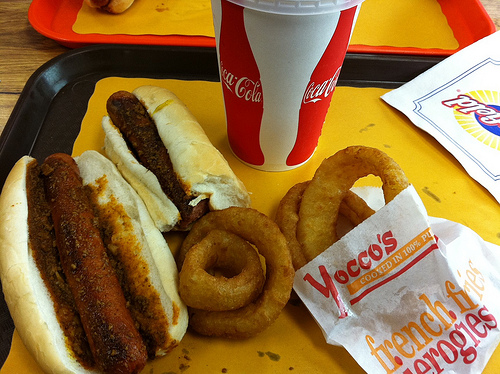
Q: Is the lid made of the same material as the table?
A: No, the lid is made of plastic and the table is made of wood.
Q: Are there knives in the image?
A: No, there are no knives.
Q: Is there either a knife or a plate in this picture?
A: No, there are no knives or plates.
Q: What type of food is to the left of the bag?
A: The food is onion rings.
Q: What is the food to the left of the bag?
A: The food is onion rings.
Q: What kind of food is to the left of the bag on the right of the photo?
A: The food is onion rings.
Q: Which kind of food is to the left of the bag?
A: The food is onion rings.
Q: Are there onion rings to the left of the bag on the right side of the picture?
A: Yes, there are onion rings to the left of the bag.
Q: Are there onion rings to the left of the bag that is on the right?
A: Yes, there are onion rings to the left of the bag.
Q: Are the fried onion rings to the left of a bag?
A: Yes, the onion rings are to the left of a bag.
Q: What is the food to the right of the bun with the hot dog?
A: The food is onion rings.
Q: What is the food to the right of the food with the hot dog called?
A: The food is onion rings.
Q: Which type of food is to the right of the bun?
A: The food is onion rings.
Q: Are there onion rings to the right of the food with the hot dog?
A: Yes, there are onion rings to the right of the bun.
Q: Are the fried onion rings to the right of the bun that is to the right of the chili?
A: Yes, the onion rings are to the right of the bun.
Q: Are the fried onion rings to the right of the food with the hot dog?
A: Yes, the onion rings are to the right of the bun.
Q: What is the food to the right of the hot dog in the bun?
A: The food is onion rings.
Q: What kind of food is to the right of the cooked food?
A: The food is onion rings.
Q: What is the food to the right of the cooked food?
A: The food is onion rings.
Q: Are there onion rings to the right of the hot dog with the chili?
A: Yes, there are onion rings to the right of the hot dog.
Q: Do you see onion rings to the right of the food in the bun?
A: Yes, there are onion rings to the right of the hot dog.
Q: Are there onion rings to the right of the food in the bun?
A: Yes, there are onion rings to the right of the hot dog.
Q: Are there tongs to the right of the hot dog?
A: No, there are onion rings to the right of the hot dog.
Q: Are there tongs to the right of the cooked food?
A: No, there are onion rings to the right of the hot dog.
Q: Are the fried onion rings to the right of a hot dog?
A: Yes, the onion rings are to the right of a hot dog.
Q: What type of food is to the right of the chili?
A: The food is onion rings.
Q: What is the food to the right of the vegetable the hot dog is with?
A: The food is onion rings.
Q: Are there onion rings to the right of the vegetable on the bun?
A: Yes, there are onion rings to the right of the chili.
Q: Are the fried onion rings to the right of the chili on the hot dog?
A: Yes, the onion rings are to the right of the chili.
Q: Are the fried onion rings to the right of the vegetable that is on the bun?
A: Yes, the onion rings are to the right of the chili.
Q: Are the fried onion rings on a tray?
A: Yes, the onion rings are on a tray.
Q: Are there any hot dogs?
A: Yes, there is a hot dog.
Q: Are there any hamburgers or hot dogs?
A: Yes, there is a hot dog.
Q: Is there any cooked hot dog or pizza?
A: Yes, there is a cooked hot dog.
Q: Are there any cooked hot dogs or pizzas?
A: Yes, there is a cooked hot dog.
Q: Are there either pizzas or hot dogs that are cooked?
A: Yes, the hot dog is cooked.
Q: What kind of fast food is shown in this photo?
A: The fast food is a hot dog.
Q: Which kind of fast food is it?
A: The food is a hot dog.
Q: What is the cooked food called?
A: The food is a hot dog.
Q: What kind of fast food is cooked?
A: The fast food is a hot dog.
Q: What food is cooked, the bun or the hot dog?
A: The hot dog is cooked.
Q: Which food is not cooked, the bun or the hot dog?
A: The bun is not cooked.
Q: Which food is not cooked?
A: The food is a bun.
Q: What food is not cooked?
A: The food is a bun.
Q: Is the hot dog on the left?
A: Yes, the hot dog is on the left of the image.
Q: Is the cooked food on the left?
A: Yes, the hot dog is on the left of the image.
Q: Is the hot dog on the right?
A: No, the hot dog is on the left of the image.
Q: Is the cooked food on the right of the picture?
A: No, the hot dog is on the left of the image.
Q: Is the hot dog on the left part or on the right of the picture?
A: The hot dog is on the left of the image.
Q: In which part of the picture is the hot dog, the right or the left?
A: The hot dog is on the left of the image.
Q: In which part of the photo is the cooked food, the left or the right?
A: The hot dog is on the left of the image.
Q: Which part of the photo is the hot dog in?
A: The hot dog is on the left of the image.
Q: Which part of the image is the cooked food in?
A: The hot dog is on the left of the image.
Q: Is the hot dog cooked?
A: Yes, the hot dog is cooked.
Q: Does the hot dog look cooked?
A: Yes, the hot dog is cooked.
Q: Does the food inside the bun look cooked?
A: Yes, the hot dog is cooked.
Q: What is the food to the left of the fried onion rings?
A: The food is a hot dog.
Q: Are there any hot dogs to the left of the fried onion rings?
A: Yes, there is a hot dog to the left of the onion rings.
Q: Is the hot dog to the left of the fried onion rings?
A: Yes, the hot dog is to the left of the onion rings.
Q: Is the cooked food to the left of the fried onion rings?
A: Yes, the hot dog is to the left of the onion rings.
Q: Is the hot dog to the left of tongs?
A: No, the hot dog is to the left of the onion rings.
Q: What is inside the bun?
A: The hot dog is inside the bun.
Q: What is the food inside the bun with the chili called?
A: The food is a hot dog.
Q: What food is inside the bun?
A: The food is a hot dog.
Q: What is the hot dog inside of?
A: The hot dog is inside the bun.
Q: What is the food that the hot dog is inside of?
A: The food is a bun.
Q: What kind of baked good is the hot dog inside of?
A: The hot dog is inside the bun.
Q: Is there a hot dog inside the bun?
A: Yes, there is a hot dog inside the bun.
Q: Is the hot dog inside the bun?
A: Yes, the hot dog is inside the bun.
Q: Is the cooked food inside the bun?
A: Yes, the hot dog is inside the bun.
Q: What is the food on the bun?
A: The food is a hot dog.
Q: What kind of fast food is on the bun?
A: The food is a hot dog.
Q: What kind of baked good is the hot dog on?
A: The hot dog is on the bun.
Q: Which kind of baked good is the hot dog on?
A: The hot dog is on the bun.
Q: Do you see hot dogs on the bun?
A: Yes, there is a hot dog on the bun.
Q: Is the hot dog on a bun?
A: Yes, the hot dog is on a bun.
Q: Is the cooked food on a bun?
A: Yes, the hot dog is on a bun.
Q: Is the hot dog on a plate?
A: No, the hot dog is on a bun.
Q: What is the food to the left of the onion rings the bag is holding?
A: The food is a hot dog.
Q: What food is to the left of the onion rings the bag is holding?
A: The food is a hot dog.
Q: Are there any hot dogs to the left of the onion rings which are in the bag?
A: Yes, there is a hot dog to the left of the onion rings.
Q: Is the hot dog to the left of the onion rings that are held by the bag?
A: Yes, the hot dog is to the left of the onion rings.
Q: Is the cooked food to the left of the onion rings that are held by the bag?
A: Yes, the hot dog is to the left of the onion rings.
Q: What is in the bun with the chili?
A: The hot dog is in the bun.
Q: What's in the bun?
A: The hot dog is in the bun.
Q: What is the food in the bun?
A: The food is a hot dog.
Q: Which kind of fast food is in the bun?
A: The food is a hot dog.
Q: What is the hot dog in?
A: The hot dog is in the bun.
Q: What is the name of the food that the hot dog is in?
A: The food is a bun.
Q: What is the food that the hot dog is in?
A: The food is a bun.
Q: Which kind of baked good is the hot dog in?
A: The hot dog is in the bun.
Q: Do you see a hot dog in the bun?
A: Yes, there is a hot dog in the bun.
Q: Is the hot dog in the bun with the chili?
A: Yes, the hot dog is in the bun.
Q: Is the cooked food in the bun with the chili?
A: Yes, the hot dog is in the bun.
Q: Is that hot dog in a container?
A: No, the hot dog is in the bun.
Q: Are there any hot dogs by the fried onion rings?
A: Yes, there is a hot dog by the onion rings.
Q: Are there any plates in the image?
A: No, there are no plates.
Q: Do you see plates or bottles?
A: No, there are no plates or bottles.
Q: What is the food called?
A: The food is a bun.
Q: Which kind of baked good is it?
A: The food is a bun.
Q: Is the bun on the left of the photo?
A: Yes, the bun is on the left of the image.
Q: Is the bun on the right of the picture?
A: No, the bun is on the left of the image.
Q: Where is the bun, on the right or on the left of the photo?
A: The bun is on the left of the image.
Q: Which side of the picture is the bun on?
A: The bun is on the left of the image.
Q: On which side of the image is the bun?
A: The bun is on the left of the image.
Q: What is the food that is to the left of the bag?
A: The food is a bun.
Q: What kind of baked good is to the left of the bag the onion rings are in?
A: The food is a bun.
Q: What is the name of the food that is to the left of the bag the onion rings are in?
A: The food is a bun.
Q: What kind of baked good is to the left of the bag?
A: The food is a bun.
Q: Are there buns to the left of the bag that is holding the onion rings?
A: Yes, there is a bun to the left of the bag.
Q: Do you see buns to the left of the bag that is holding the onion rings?
A: Yes, there is a bun to the left of the bag.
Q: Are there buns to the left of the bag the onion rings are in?
A: Yes, there is a bun to the left of the bag.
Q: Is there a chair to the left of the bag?
A: No, there is a bun to the left of the bag.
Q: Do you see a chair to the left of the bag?
A: No, there is a bun to the left of the bag.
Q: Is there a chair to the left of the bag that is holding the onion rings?
A: No, there is a bun to the left of the bag.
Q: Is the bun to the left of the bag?
A: Yes, the bun is to the left of the bag.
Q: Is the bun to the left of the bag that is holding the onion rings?
A: Yes, the bun is to the left of the bag.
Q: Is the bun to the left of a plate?
A: No, the bun is to the left of the bag.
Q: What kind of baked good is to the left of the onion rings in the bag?
A: The food is a bun.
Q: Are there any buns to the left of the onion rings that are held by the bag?
A: Yes, there is a bun to the left of the onion rings.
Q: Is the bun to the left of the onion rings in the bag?
A: Yes, the bun is to the left of the onion rings.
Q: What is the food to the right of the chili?
A: The food is a bun.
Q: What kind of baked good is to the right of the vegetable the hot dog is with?
A: The food is a bun.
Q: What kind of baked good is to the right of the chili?
A: The food is a bun.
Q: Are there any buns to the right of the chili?
A: Yes, there is a bun to the right of the chili.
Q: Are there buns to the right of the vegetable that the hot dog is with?
A: Yes, there is a bun to the right of the chili.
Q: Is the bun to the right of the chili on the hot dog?
A: Yes, the bun is to the right of the chili.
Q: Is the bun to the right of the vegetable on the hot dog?
A: Yes, the bun is to the right of the chili.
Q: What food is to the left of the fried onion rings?
A: The food is a bun.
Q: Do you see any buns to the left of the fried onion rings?
A: Yes, there is a bun to the left of the onion rings.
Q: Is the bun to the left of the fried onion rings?
A: Yes, the bun is to the left of the onion rings.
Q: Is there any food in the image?
A: Yes, there is food.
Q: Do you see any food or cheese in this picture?
A: Yes, there is food.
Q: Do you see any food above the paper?
A: Yes, there is food above the paper.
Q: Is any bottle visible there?
A: No, there are no bottles.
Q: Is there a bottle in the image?
A: No, there are no bottles.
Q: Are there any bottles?
A: No, there are no bottles.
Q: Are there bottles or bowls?
A: No, there are no bottles or bowls.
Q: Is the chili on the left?
A: Yes, the chili is on the left of the image.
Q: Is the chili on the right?
A: No, the chili is on the left of the image.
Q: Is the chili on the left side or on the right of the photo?
A: The chili is on the left of the image.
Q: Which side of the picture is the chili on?
A: The chili is on the left of the image.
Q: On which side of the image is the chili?
A: The chili is on the left of the image.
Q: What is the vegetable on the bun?
A: The vegetable is chili.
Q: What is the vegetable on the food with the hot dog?
A: The vegetable is chili.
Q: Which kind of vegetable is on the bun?
A: The vegetable is chili.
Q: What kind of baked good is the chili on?
A: The chili is on the bun.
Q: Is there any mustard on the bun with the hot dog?
A: No, there is chili on the bun.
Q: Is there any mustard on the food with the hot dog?
A: No, there is chili on the bun.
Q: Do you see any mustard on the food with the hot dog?
A: No, there is chili on the bun.